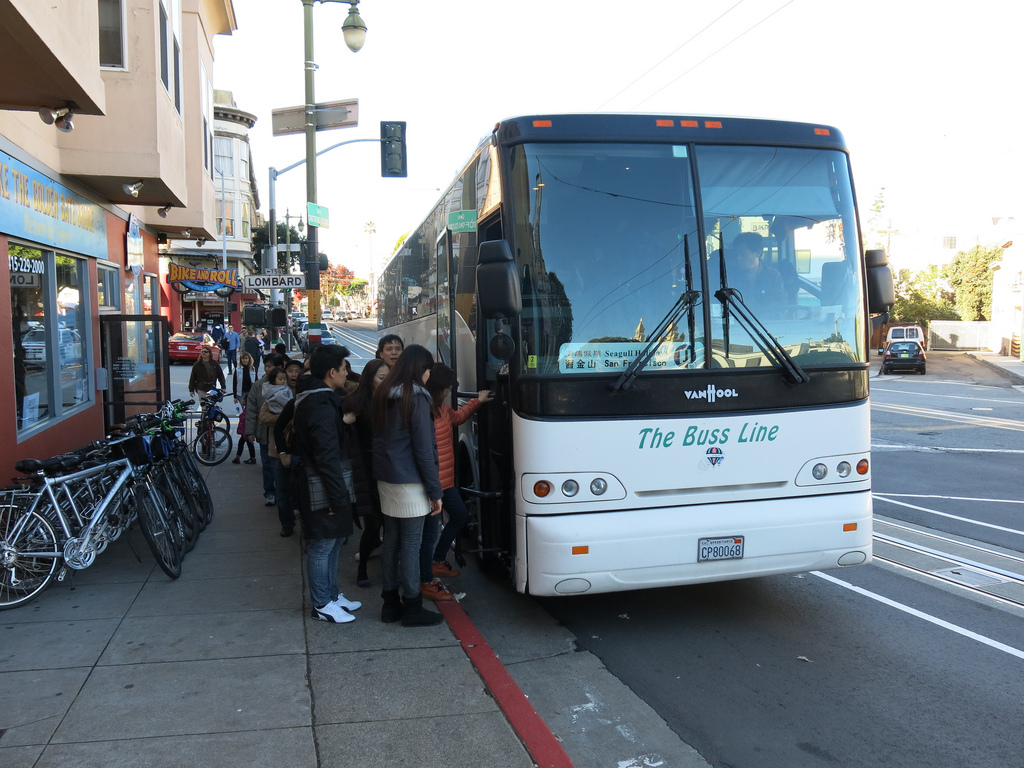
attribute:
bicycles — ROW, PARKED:
[3, 390, 211, 646]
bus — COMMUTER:
[509, 145, 883, 563]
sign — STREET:
[287, 182, 344, 241]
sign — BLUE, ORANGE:
[170, 255, 235, 288]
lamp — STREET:
[327, 1, 384, 45]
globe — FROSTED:
[349, 39, 363, 44]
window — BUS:
[559, 145, 812, 318]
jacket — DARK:
[301, 396, 345, 489]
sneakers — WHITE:
[317, 571, 359, 628]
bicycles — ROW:
[85, 433, 187, 555]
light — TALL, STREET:
[241, 3, 391, 285]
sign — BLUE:
[18, 191, 112, 252]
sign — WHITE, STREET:
[237, 266, 333, 295]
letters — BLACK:
[237, 279, 296, 284]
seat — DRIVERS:
[675, 243, 712, 313]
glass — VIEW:
[589, 163, 691, 323]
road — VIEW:
[734, 644, 953, 753]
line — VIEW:
[474, 677, 524, 723]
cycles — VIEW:
[14, 418, 213, 648]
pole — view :
[272, 7, 368, 658]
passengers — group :
[149, 245, 456, 654]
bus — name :
[620, 424, 791, 463]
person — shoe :
[313, 569, 370, 641]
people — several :
[200, 269, 466, 646]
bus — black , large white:
[376, 96, 897, 634]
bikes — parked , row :
[26, 370, 256, 625]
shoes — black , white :
[307, 575, 370, 632]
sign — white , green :
[267, 85, 389, 161]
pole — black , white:
[287, 5, 337, 628]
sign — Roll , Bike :
[267, 83, 421, 341]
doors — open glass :
[466, 281, 525, 580]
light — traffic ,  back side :
[293, 9, 374, 51]